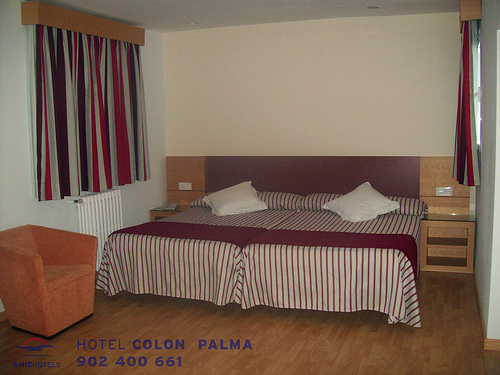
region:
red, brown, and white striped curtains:
[32, 27, 148, 203]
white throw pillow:
[205, 177, 266, 218]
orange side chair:
[1, 224, 98, 339]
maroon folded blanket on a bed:
[121, 220, 414, 250]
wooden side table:
[420, 212, 477, 279]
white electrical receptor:
[175, 176, 195, 198]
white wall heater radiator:
[71, 192, 128, 227]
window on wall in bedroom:
[467, 38, 487, 148]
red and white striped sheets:
[249, 245, 419, 324]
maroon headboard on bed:
[204, 155, 423, 195]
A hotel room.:
[25, 8, 470, 349]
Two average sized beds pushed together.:
[105, 145, 431, 330]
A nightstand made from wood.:
[417, 202, 482, 297]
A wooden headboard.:
[167, 145, 474, 201]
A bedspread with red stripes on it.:
[110, 185, 416, 305]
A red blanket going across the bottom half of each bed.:
[115, 215, 415, 255]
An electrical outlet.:
[425, 185, 455, 200]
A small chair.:
[0, 201, 100, 343]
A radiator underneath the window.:
[67, 182, 143, 257]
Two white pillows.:
[198, 175, 393, 220]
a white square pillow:
[318, 166, 403, 227]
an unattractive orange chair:
[2, 210, 109, 338]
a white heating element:
[58, 181, 160, 279]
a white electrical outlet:
[431, 179, 461, 210]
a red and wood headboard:
[157, 137, 484, 276]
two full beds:
[157, 175, 436, 315]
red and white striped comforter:
[243, 184, 447, 340]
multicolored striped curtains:
[26, 57, 164, 209]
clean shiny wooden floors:
[75, 253, 485, 369]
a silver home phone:
[158, 197, 185, 214]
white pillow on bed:
[202, 171, 269, 226]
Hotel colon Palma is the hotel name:
[75, 327, 269, 358]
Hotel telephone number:
[72, 348, 185, 373]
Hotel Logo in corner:
[2, 325, 65, 374]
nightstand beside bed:
[149, 192, 196, 228]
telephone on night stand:
[153, 196, 181, 212]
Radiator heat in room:
[57, 185, 137, 277]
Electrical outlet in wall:
[159, 168, 204, 194]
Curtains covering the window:
[16, 2, 158, 210]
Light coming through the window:
[472, 22, 489, 164]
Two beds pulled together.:
[103, 181, 420, 343]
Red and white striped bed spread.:
[263, 185, 412, 322]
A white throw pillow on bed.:
[313, 177, 397, 229]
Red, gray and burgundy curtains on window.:
[30, 29, 157, 203]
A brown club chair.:
[3, 224, 120, 344]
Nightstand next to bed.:
[418, 188, 479, 278]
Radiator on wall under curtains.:
[66, 181, 139, 273]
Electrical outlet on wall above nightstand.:
[432, 181, 457, 202]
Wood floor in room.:
[267, 324, 456, 366]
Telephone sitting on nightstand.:
[156, 193, 182, 213]